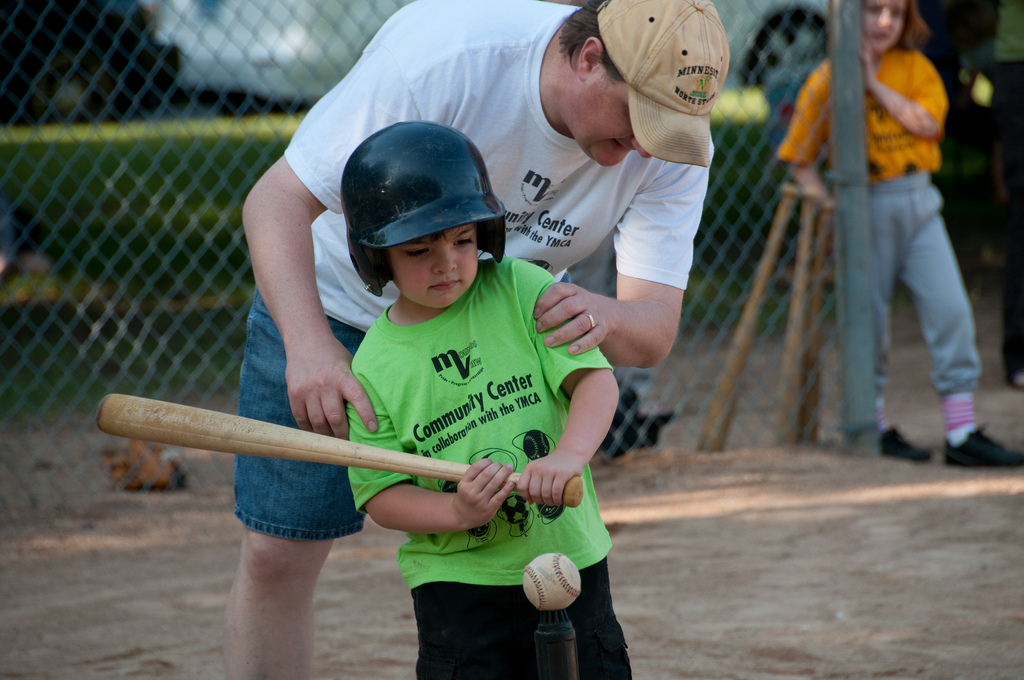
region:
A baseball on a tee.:
[519, 550, 584, 614]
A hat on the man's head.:
[569, 2, 731, 167]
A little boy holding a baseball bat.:
[96, 120, 634, 677]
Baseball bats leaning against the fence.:
[690, 180, 839, 453]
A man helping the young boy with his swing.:
[229, 0, 727, 675]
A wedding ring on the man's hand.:
[582, 309, 599, 329]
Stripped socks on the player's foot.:
[937, 386, 979, 444]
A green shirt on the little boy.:
[342, 259, 615, 585]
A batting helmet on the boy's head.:
[339, 119, 513, 300]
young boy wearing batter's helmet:
[328, 115, 635, 672]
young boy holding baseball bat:
[93, 116, 634, 676]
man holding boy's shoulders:
[222, 0, 731, 678]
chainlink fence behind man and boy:
[12, 0, 831, 510]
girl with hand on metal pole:
[774, 0, 1019, 472]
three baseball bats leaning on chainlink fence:
[700, 179, 847, 451]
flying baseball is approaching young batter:
[333, 115, 641, 676]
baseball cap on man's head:
[539, 5, 743, 171]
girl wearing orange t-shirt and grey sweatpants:
[777, 0, 1021, 476]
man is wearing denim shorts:
[219, 2, 736, 676]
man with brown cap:
[238, 1, 735, 676]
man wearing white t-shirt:
[226, 4, 736, 676]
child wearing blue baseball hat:
[334, 111, 641, 677]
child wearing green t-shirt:
[339, 115, 641, 676]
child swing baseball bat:
[91, 118, 635, 676]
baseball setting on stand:
[514, 545, 590, 676]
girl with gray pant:
[772, 0, 1016, 468]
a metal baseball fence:
[4, 0, 889, 510]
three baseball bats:
[690, 175, 842, 460]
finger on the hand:
[354, 386, 375, 425]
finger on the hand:
[333, 417, 360, 444]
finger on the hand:
[313, 417, 329, 433]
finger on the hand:
[285, 383, 304, 422]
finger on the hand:
[536, 304, 566, 325]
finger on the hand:
[512, 290, 560, 309]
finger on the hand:
[542, 480, 556, 491]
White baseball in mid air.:
[506, 543, 579, 610]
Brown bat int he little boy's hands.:
[90, 373, 593, 536]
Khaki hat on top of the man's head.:
[593, 0, 721, 172]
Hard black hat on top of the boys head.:
[336, 122, 499, 300]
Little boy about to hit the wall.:
[315, 92, 607, 674]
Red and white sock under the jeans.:
[933, 382, 1006, 460]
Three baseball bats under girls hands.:
[728, 148, 853, 452]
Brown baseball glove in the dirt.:
[102, 426, 201, 490]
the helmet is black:
[345, 123, 507, 286]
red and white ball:
[523, 554, 582, 608]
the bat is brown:
[92, 397, 587, 506]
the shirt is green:
[346, 255, 612, 576]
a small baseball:
[513, 550, 594, 611]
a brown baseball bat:
[95, 386, 593, 508]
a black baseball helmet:
[337, 127, 525, 299]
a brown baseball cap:
[588, 2, 741, 168]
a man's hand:
[282, 331, 382, 443]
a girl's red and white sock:
[936, 385, 982, 444]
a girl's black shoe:
[939, 427, 1017, 467]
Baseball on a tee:
[496, 546, 602, 670]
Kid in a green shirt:
[167, 132, 695, 651]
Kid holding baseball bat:
[226, 127, 691, 669]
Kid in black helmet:
[214, 89, 709, 662]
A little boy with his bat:
[89, 118, 634, 676]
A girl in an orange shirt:
[775, 1, 1022, 466]